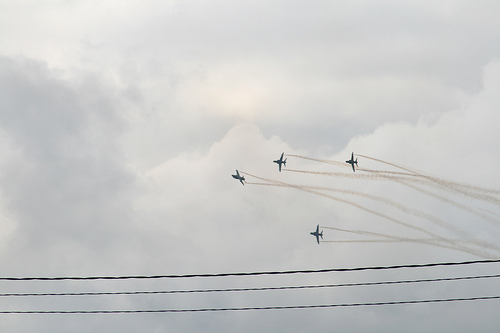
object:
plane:
[231, 170, 245, 186]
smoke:
[240, 169, 491, 258]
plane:
[344, 150, 361, 173]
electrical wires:
[1, 295, 500, 314]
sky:
[0, 1, 500, 332]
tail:
[283, 159, 289, 167]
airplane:
[272, 152, 291, 170]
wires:
[0, 256, 500, 281]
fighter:
[311, 224, 325, 244]